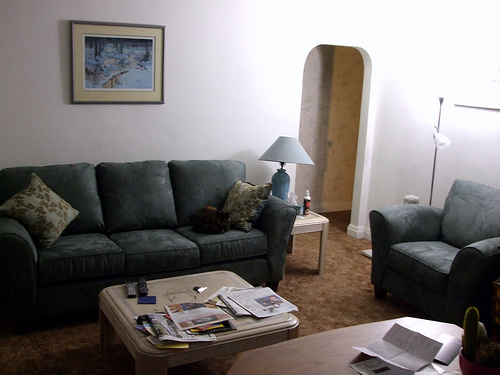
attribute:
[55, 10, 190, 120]
picture — hanging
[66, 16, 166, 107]
picture frame — large 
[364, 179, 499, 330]
chair — green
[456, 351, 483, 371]
pot — red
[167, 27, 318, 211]
wall — white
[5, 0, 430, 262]
wall — white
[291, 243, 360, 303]
carpet — brown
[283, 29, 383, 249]
doorway — arched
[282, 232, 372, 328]
carpet — brown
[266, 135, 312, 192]
lamp — blue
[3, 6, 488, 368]
living room — gray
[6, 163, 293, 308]
couch — long, gray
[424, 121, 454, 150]
lamp — white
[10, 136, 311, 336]
sofa — large, green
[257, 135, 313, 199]
lamp — blue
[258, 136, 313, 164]
shade — white